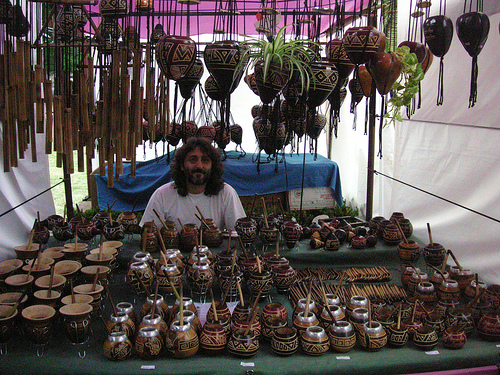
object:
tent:
[0, 0, 499, 368]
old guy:
[166, 129, 227, 202]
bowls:
[229, 301, 398, 361]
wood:
[313, 253, 406, 304]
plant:
[219, 22, 326, 109]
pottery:
[1, 210, 498, 354]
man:
[139, 138, 246, 228]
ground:
[411, 157, 446, 195]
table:
[238, 150, 344, 208]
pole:
[351, 4, 398, 218]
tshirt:
[140, 188, 272, 228]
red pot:
[362, 52, 402, 94]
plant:
[383, 41, 424, 125]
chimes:
[41, 40, 161, 187]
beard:
[183, 165, 211, 186]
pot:
[320, 293, 398, 352]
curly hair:
[157, 130, 230, 190]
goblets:
[0, 233, 124, 369]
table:
[2, 345, 494, 371]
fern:
[230, 21, 327, 102]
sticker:
[331, 352, 356, 362]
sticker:
[421, 342, 444, 359]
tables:
[283, 347, 441, 372]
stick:
[316, 273, 335, 303]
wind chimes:
[103, 7, 434, 142]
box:
[285, 187, 337, 209]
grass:
[238, 192, 360, 216]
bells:
[1, 27, 175, 200]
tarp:
[93, 141, 343, 209]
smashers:
[292, 247, 414, 303]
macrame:
[149, 2, 469, 117]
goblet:
[59, 300, 93, 354]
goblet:
[18, 302, 56, 358]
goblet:
[79, 261, 111, 305]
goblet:
[0, 269, 36, 301]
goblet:
[86, 245, 116, 286]